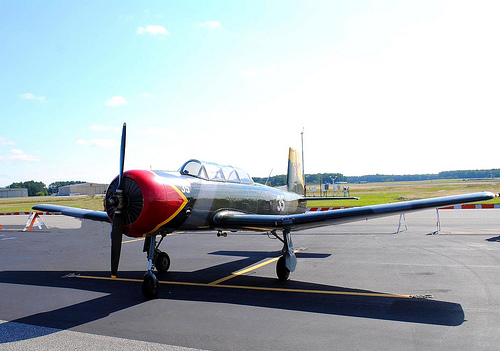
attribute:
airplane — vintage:
[37, 93, 483, 295]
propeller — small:
[93, 117, 147, 283]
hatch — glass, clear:
[173, 150, 258, 188]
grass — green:
[1, 178, 499, 209]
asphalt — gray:
[6, 205, 500, 350]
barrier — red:
[1, 211, 61, 232]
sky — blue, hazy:
[1, 2, 493, 184]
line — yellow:
[69, 264, 410, 310]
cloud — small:
[17, 88, 48, 110]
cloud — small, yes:
[135, 20, 173, 41]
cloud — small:
[103, 90, 131, 113]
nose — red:
[105, 168, 185, 240]